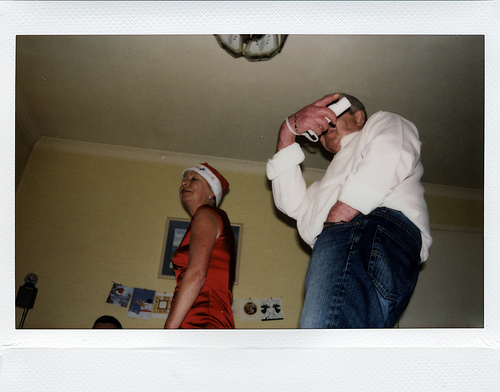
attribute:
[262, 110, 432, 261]
shirt — long sleeved, white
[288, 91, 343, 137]
remote control — wii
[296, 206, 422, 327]
jeans — blue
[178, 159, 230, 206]
santa hat — santa clause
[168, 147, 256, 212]
head — woman's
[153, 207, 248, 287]
picture — framed